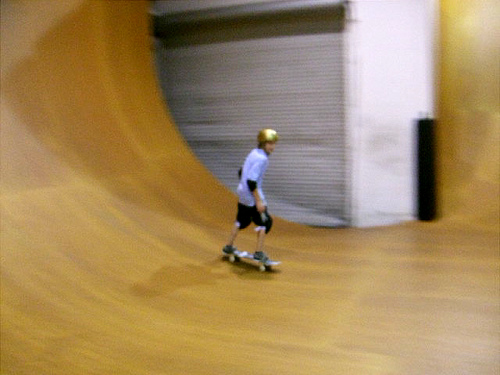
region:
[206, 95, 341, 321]
the boy is skateboarding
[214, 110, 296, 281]
the boy is skateboarding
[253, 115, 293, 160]
the helmet is gold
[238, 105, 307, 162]
the helmet is gold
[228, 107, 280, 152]
boy wearing a gold helmet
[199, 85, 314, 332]
boy wearing a gold helmet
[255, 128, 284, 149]
a golden helmet on his head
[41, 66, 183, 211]
a wooden ramp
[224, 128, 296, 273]
a boy riding a skate board on a wooden ramp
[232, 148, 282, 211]
a blue and black shirt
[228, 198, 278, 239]
black and white shorts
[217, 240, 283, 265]
black and white sneakers on a skate board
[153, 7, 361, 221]
a metal roll down gate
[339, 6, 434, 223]
a white dirty wall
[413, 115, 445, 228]
a black door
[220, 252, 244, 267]
a skate board wheel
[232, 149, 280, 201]
the shirt is blue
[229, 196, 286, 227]
the shorts are black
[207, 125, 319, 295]
the guy is on a skateboard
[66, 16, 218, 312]
the surface is curved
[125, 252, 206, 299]
shadow is on the ground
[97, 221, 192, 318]
the surface is wooden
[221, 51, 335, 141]
the gate is mettalic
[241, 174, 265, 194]
the elbow sleeves are black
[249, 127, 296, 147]
the helmet is golden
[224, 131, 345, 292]
the sport is indoors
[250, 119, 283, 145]
He has a gold helmet.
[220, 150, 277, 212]
He has a blue shirt.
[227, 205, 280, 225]
He is wearing black pants.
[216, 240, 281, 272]
He has black shoes on.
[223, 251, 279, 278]
The skateboard is brown.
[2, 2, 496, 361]
The half pipe is brown.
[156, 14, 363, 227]
The door is grey.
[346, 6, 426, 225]
The wall is white.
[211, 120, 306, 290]
He is skateboarding.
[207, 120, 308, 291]
He is moving.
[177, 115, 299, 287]
A man riding on a skateboard ramp.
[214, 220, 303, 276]
A skateboard on a ramp.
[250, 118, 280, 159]
a helmet on a man.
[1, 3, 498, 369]
A large wooden skateboard ramp.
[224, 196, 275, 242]
a pair of black shorts.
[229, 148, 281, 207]
a man wearing a blue shirt.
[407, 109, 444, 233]
a dark doorway.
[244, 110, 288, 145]
a man in a helmet.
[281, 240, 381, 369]
a light spot on a wooden ramp.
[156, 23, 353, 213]
a wall near a wooden ramp.